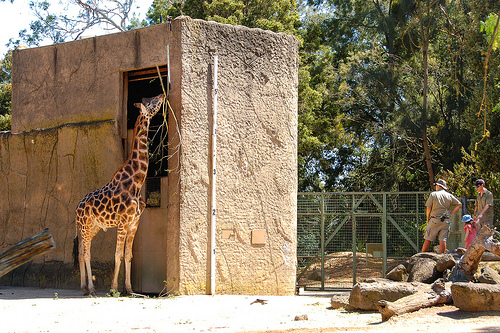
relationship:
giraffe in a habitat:
[75, 94, 164, 298] [0, 14, 498, 332]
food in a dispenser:
[163, 96, 172, 105] [161, 90, 173, 110]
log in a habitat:
[379, 286, 452, 315] [0, 14, 498, 332]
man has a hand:
[423, 179, 463, 254] [427, 215, 430, 223]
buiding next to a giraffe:
[11, 15, 297, 298] [75, 94, 164, 298]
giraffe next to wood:
[75, 94, 164, 298] [379, 279, 451, 319]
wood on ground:
[379, 279, 451, 319] [1, 285, 499, 332]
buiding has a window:
[11, 15, 297, 298] [125, 68, 169, 207]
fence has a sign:
[297, 192, 499, 290] [364, 241, 383, 258]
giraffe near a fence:
[75, 94, 164, 298] [297, 192, 499, 290]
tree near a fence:
[149, 2, 351, 189] [297, 192, 499, 290]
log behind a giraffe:
[379, 286, 452, 315] [75, 94, 164, 298]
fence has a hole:
[297, 192, 499, 290] [358, 203, 364, 210]